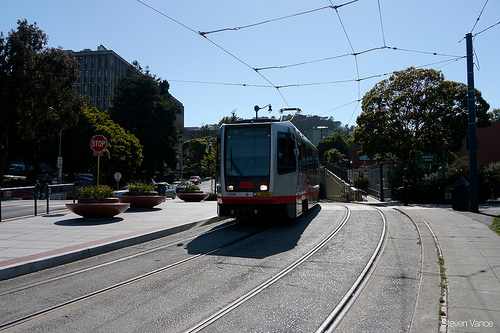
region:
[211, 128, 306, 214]
silver and red train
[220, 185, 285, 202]
red stripe on train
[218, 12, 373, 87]
black wires in sky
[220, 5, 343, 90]
black train wires attached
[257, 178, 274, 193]
front light on train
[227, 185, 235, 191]
front light on train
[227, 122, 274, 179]
front window on train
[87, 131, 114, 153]
red stop sign on pole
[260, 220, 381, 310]
metal tracks built into road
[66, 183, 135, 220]
planter with bushes in them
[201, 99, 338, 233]
a muni train passing by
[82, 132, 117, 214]
a stop sign on street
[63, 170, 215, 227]
outdoor plants on the side street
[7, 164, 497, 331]
main street and road for car and muni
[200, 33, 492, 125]
bunch of power lines in a net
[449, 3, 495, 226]
a power pole on street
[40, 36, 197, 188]
a tall facility building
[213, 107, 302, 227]
the front of a muni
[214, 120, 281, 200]
windshield of a muni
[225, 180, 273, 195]
front head lights of muni car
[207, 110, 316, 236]
light rail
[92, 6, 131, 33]
white clouds in blue sky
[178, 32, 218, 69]
white clouds in blue sky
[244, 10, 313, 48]
white clouds in blue sky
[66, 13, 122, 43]
white clouds in blue sky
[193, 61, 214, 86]
white clouds in blue sky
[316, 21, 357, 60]
white clouds in blue sky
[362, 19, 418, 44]
white clouds in blue sky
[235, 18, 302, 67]
white clouds in blue sky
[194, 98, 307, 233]
front part of the train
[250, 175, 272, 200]
light of the train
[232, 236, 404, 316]
a empty rail way track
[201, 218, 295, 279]
shadow of the train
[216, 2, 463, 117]
a electric wires in sky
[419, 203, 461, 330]
a small white line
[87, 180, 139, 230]
a large pot of tree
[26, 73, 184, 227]
a group of trees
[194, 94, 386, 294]
a train in the track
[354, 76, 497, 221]
a large tree near track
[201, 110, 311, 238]
back door the train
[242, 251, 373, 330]
a rail way track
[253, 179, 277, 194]
a white light on train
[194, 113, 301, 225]
a train in track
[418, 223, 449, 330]
a white hole in road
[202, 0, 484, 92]
a wire in sky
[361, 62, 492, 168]
a very big tree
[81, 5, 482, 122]
a beautiful view of sky